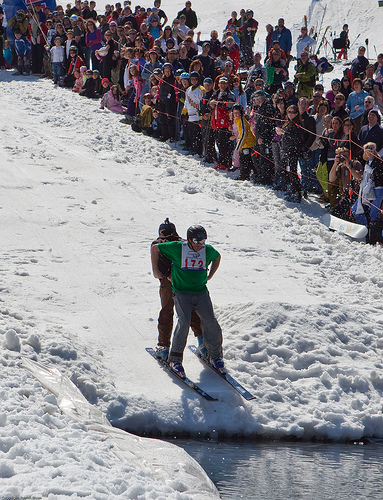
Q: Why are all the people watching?
A: It's a competition.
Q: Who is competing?
A: Skiers.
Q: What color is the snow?
A: White.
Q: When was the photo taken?
A: In the daytime.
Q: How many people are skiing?
A: Two.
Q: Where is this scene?
A: On a ski hill.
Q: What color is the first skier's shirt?
A: Green.